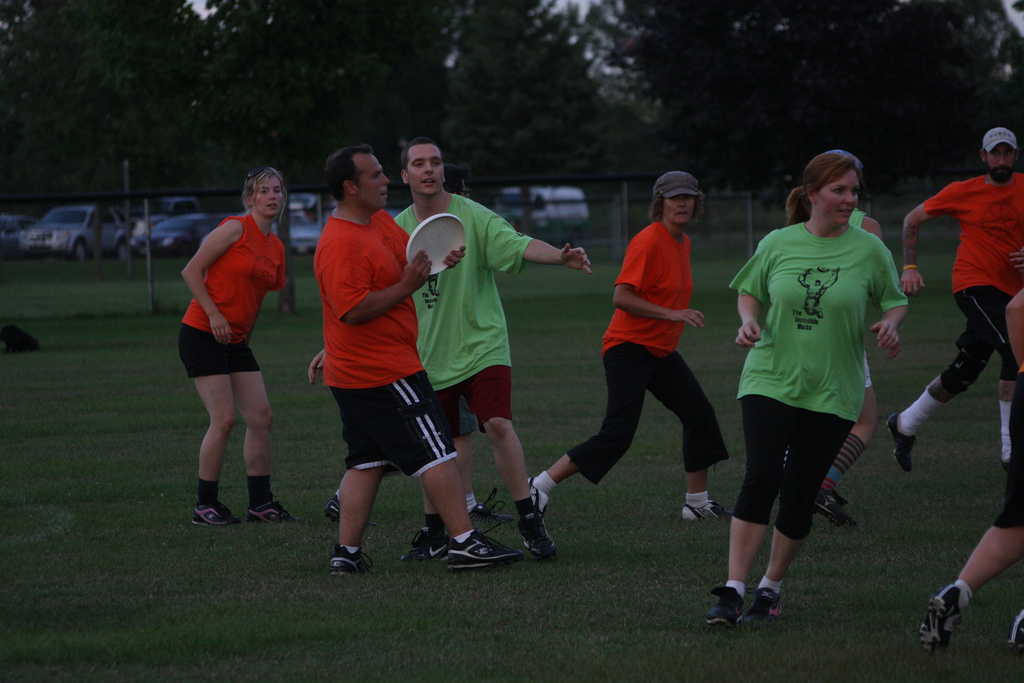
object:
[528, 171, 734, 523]
woman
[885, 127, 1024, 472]
man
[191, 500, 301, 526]
shoes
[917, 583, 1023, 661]
shoes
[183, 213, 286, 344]
shirt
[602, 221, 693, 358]
shirt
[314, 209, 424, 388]
shirt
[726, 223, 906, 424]
shirt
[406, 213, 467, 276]
frisbee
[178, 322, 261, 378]
shorts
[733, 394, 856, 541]
capris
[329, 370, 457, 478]
shorts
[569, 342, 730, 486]
pants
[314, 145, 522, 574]
man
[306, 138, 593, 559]
man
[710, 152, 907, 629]
woman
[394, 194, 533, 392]
shirt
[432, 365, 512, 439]
shorts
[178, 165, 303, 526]
woman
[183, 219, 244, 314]
arm